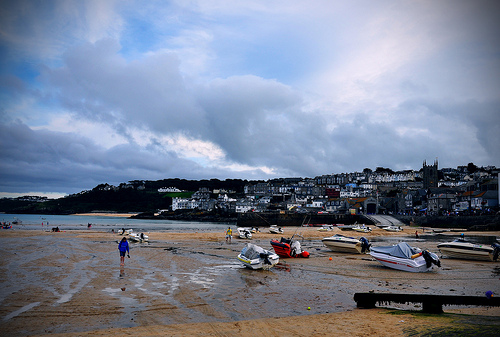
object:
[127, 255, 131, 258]
shoe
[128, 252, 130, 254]
hand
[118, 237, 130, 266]
person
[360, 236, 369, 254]
person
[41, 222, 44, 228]
person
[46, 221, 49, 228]
person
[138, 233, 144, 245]
person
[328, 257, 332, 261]
roundobject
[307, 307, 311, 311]
roundobject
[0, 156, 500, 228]
ocean city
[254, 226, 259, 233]
person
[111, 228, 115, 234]
person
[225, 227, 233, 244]
person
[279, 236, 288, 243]
person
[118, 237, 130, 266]
woman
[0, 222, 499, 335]
beach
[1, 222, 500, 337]
shore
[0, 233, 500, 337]
low tide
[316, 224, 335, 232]
boats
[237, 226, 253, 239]
boats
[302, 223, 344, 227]
boats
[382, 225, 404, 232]
boats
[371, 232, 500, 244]
boats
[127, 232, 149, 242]
boats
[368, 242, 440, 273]
boat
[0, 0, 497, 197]
clouds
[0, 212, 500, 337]
land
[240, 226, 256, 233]
boat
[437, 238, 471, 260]
boat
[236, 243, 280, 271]
boat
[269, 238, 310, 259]
boat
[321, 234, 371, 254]
boat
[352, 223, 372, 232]
boat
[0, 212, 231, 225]
water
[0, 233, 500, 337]
water